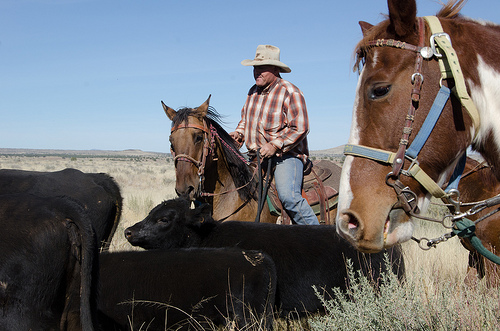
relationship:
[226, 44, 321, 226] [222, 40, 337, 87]
cowboy wearing hat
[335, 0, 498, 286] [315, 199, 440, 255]
horse has mouth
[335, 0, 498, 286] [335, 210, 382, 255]
horse has nose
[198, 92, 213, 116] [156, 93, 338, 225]
ear of a horse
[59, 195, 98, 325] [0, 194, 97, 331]
tail of cattle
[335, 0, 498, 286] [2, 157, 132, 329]
horse corralling cattle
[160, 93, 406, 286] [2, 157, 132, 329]
horse corralling cattle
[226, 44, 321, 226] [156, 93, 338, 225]
cowboy is mounted on horse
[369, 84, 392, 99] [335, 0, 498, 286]
eye is on horse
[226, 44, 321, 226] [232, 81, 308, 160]
cowboy wearing shirt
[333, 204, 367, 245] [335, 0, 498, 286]
nose of a horse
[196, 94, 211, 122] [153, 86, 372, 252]
ear of horse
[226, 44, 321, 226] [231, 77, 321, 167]
cowboy has shirt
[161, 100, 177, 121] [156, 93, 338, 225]
ear of horse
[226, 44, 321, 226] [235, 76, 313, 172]
cowboy wearing shirt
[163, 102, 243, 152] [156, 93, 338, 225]
mane on horse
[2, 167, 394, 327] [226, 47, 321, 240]
cattle in front of cowboy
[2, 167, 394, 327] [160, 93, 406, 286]
cattle in front of horse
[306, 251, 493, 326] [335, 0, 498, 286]
weeds next to horse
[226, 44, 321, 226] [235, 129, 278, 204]
cowboy holding reins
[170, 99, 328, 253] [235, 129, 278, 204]
horse has reins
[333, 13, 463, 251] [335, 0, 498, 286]
head on horse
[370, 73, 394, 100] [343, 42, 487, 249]
eye on horse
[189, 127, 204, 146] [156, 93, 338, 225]
eye on horse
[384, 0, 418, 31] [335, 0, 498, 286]
ear on horse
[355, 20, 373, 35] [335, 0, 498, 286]
ear on horse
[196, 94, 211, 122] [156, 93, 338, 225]
ear on horse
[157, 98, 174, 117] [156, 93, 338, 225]
ear on horse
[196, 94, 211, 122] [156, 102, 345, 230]
ear on horse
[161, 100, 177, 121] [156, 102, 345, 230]
ear on horse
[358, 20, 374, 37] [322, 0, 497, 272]
ear on horse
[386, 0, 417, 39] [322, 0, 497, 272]
ear on horse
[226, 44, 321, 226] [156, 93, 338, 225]
cowboy riding horse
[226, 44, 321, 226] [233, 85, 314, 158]
cowboy wearing shirt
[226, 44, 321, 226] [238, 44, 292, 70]
cowboy wearing hat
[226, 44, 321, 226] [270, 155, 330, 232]
cowboy wearing jeans